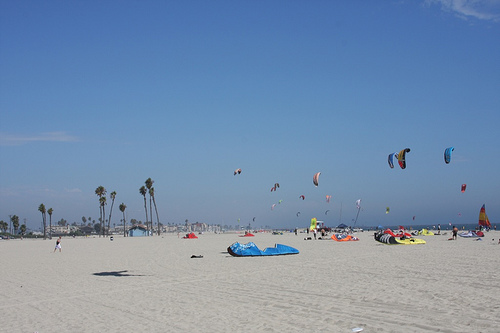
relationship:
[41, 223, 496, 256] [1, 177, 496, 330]
people enjoying beach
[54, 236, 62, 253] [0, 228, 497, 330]
people playing in sand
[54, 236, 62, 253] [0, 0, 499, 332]
people enjoying sunshine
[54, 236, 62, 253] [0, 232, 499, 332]
people at beach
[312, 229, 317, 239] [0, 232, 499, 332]
person at beach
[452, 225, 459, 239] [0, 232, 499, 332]
people at beach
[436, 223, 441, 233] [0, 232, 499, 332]
person at beach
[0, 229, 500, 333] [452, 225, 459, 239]
beach has people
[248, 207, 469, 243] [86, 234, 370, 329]
people playing on beach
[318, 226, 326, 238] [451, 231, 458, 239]
person wears shorts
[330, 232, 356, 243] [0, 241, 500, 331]
structure in sand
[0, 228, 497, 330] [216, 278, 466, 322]
sand has tracks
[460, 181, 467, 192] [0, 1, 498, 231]
kite in sky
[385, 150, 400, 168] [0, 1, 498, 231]
kite in sky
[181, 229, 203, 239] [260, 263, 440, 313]
kite on beach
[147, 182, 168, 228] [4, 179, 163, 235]
palm tree in grove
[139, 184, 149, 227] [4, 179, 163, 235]
palm tree in grove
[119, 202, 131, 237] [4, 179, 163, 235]
palm tree in grove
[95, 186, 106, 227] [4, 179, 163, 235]
palm tree in grove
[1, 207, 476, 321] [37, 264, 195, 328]
beach has sand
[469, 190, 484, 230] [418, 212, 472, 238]
sailboat on water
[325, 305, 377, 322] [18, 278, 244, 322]
track in sand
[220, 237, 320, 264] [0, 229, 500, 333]
kite on beach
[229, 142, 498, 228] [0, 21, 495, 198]
kites flying in air